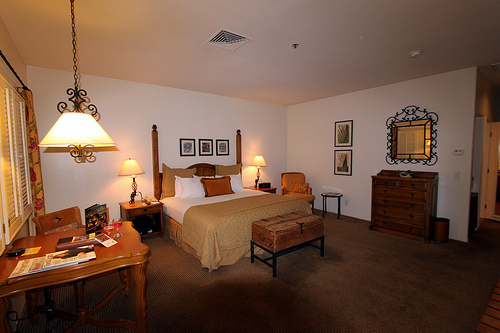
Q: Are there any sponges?
A: No, there are no sponges.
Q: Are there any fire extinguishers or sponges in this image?
A: No, there are no sponges or fire extinguishers.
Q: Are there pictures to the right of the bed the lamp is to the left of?
A: Yes, there is a picture to the right of the bed.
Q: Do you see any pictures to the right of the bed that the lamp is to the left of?
A: Yes, there is a picture to the right of the bed.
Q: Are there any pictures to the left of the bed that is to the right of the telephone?
A: No, the picture is to the right of the bed.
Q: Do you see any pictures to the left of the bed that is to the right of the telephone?
A: No, the picture is to the right of the bed.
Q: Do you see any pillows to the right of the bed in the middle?
A: No, there is a picture to the right of the bed.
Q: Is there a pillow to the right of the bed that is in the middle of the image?
A: No, there is a picture to the right of the bed.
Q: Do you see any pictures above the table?
A: Yes, there is a picture above the table.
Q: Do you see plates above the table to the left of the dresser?
A: No, there is a picture above the table.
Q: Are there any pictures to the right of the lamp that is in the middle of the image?
A: Yes, there is a picture to the right of the lamp.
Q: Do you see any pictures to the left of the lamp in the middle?
A: No, the picture is to the right of the lamp.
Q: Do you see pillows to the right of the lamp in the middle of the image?
A: No, there is a picture to the right of the lamp.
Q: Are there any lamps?
A: Yes, there is a lamp.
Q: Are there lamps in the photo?
A: Yes, there is a lamp.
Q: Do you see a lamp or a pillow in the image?
A: Yes, there is a lamp.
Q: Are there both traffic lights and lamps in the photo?
A: No, there is a lamp but no traffic lights.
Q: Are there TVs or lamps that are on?
A: Yes, the lamp is on.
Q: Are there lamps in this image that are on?
A: Yes, there is a lamp that is on.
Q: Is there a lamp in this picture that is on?
A: Yes, there is a lamp that is on.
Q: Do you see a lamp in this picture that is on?
A: Yes, there is a lamp that is on.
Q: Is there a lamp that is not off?
A: Yes, there is a lamp that is on.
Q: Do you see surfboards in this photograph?
A: No, there are no surfboards.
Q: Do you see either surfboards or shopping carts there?
A: No, there are no surfboards or shopping carts.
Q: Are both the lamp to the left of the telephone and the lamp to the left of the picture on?
A: Yes, both the lamp and the lamp are on.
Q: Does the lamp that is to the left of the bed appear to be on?
A: Yes, the lamp is on.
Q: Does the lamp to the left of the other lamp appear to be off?
A: No, the lamp is on.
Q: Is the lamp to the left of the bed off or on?
A: The lamp is on.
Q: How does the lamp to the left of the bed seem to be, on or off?
A: The lamp is on.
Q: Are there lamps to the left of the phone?
A: Yes, there is a lamp to the left of the phone.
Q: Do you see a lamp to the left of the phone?
A: Yes, there is a lamp to the left of the phone.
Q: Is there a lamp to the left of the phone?
A: Yes, there is a lamp to the left of the phone.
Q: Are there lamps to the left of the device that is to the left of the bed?
A: Yes, there is a lamp to the left of the phone.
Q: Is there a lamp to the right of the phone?
A: No, the lamp is to the left of the phone.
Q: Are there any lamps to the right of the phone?
A: No, the lamp is to the left of the phone.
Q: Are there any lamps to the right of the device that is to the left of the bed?
A: No, the lamp is to the left of the phone.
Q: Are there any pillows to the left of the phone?
A: No, there is a lamp to the left of the phone.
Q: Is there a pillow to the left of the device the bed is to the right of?
A: No, there is a lamp to the left of the phone.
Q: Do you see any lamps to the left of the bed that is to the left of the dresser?
A: Yes, there is a lamp to the left of the bed.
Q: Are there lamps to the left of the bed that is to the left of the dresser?
A: Yes, there is a lamp to the left of the bed.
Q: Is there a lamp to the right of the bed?
A: No, the lamp is to the left of the bed.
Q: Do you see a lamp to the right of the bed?
A: No, the lamp is to the left of the bed.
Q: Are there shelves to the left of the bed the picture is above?
A: No, there is a lamp to the left of the bed.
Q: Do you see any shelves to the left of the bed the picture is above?
A: No, there is a lamp to the left of the bed.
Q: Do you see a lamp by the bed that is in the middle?
A: Yes, there is a lamp by the bed.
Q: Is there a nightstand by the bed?
A: No, there is a lamp by the bed.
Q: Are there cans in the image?
A: Yes, there is a can.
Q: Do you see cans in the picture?
A: Yes, there is a can.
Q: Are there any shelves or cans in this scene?
A: Yes, there is a can.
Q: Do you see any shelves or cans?
A: Yes, there is a can.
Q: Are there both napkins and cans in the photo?
A: No, there is a can but no napkins.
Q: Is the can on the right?
A: Yes, the can is on the right of the image.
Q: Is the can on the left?
A: No, the can is on the right of the image.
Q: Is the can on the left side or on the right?
A: The can is on the right of the image.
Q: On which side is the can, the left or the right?
A: The can is on the right of the image.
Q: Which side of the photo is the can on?
A: The can is on the right of the image.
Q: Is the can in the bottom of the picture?
A: Yes, the can is in the bottom of the image.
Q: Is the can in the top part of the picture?
A: No, the can is in the bottom of the image.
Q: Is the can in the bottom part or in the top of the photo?
A: The can is in the bottom of the image.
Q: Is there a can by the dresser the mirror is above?
A: Yes, there is a can by the dresser.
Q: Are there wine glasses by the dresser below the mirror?
A: No, there is a can by the dresser.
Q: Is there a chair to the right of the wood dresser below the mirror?
A: No, there is a can to the right of the dresser.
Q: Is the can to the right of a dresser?
A: Yes, the can is to the right of a dresser.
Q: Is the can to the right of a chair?
A: No, the can is to the right of a dresser.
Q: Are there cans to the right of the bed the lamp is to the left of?
A: Yes, there is a can to the right of the bed.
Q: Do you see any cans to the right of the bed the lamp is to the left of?
A: Yes, there is a can to the right of the bed.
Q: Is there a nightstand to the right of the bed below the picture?
A: No, there is a can to the right of the bed.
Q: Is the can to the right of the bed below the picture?
A: Yes, the can is to the right of the bed.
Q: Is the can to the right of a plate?
A: No, the can is to the right of the bed.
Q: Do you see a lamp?
A: Yes, there is a lamp.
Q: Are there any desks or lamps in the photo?
A: Yes, there is a lamp.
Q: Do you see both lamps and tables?
A: Yes, there are both a lamp and a table.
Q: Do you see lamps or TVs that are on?
A: Yes, the lamp is on.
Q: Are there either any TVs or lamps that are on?
A: Yes, the lamp is on.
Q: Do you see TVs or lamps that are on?
A: Yes, the lamp is on.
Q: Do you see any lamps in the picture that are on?
A: Yes, there is a lamp that is on.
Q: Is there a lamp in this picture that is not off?
A: Yes, there is a lamp that is on.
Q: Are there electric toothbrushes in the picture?
A: No, there are no electric toothbrushes.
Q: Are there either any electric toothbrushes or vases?
A: No, there are no electric toothbrushes or vases.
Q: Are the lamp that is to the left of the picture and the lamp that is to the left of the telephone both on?
A: Yes, both the lamp and the lamp are on.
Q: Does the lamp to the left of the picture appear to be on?
A: Yes, the lamp is on.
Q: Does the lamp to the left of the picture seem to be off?
A: No, the lamp is on.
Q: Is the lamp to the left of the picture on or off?
A: The lamp is on.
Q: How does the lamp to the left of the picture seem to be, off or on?
A: The lamp is on.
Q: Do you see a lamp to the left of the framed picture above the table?
A: Yes, there is a lamp to the left of the picture.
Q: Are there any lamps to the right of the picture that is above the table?
A: No, the lamp is to the left of the picture.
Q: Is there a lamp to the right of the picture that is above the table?
A: No, the lamp is to the left of the picture.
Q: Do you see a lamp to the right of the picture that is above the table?
A: No, the lamp is to the left of the picture.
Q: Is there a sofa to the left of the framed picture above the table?
A: No, there is a lamp to the left of the picture.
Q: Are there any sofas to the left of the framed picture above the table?
A: No, there is a lamp to the left of the picture.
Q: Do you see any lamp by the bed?
A: Yes, there is a lamp by the bed.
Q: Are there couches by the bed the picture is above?
A: No, there is a lamp by the bed.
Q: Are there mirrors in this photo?
A: Yes, there is a mirror.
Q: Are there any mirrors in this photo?
A: Yes, there is a mirror.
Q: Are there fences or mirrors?
A: Yes, there is a mirror.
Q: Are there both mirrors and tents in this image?
A: No, there is a mirror but no tents.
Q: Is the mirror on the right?
A: Yes, the mirror is on the right of the image.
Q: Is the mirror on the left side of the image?
A: No, the mirror is on the right of the image.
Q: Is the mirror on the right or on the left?
A: The mirror is on the right of the image.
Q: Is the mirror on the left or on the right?
A: The mirror is on the right of the image.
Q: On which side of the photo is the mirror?
A: The mirror is on the right of the image.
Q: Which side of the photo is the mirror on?
A: The mirror is on the right of the image.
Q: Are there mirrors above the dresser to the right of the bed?
A: Yes, there is a mirror above the dresser.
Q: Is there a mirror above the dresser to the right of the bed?
A: Yes, there is a mirror above the dresser.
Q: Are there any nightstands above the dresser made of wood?
A: No, there is a mirror above the dresser.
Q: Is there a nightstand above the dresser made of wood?
A: No, there is a mirror above the dresser.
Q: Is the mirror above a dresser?
A: Yes, the mirror is above a dresser.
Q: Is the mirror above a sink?
A: No, the mirror is above a dresser.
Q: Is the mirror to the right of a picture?
A: Yes, the mirror is to the right of a picture.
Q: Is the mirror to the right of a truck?
A: No, the mirror is to the right of a picture.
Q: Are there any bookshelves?
A: No, there are no bookshelves.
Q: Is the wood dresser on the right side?
A: Yes, the dresser is on the right of the image.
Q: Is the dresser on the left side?
A: No, the dresser is on the right of the image.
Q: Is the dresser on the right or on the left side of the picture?
A: The dresser is on the right of the image.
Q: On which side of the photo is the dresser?
A: The dresser is on the right of the image.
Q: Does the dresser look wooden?
A: Yes, the dresser is wooden.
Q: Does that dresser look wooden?
A: Yes, the dresser is wooden.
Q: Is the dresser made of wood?
A: Yes, the dresser is made of wood.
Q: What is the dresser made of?
A: The dresser is made of wood.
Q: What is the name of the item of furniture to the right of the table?
A: The piece of furniture is a dresser.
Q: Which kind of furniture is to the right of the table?
A: The piece of furniture is a dresser.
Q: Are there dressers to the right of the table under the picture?
A: Yes, there is a dresser to the right of the table.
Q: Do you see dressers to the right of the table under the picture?
A: Yes, there is a dresser to the right of the table.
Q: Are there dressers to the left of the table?
A: No, the dresser is to the right of the table.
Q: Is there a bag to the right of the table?
A: No, there is a dresser to the right of the table.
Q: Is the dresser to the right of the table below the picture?
A: Yes, the dresser is to the right of the table.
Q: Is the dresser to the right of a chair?
A: No, the dresser is to the right of the table.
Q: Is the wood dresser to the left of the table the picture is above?
A: No, the dresser is to the right of the table.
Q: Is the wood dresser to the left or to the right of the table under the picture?
A: The dresser is to the right of the table.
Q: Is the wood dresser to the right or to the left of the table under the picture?
A: The dresser is to the right of the table.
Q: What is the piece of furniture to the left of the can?
A: The piece of furniture is a dresser.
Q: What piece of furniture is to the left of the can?
A: The piece of furniture is a dresser.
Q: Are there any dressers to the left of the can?
A: Yes, there is a dresser to the left of the can.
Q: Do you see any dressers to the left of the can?
A: Yes, there is a dresser to the left of the can.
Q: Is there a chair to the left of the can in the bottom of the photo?
A: No, there is a dresser to the left of the can.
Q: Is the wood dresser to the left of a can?
A: Yes, the dresser is to the left of a can.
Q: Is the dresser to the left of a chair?
A: No, the dresser is to the left of a can.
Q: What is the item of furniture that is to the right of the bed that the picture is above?
A: The piece of furniture is a dresser.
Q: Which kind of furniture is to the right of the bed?
A: The piece of furniture is a dresser.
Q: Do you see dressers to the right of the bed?
A: Yes, there is a dresser to the right of the bed.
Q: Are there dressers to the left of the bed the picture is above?
A: No, the dresser is to the right of the bed.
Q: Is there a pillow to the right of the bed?
A: No, there is a dresser to the right of the bed.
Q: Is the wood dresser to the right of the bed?
A: Yes, the dresser is to the right of the bed.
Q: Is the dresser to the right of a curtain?
A: No, the dresser is to the right of the bed.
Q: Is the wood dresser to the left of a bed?
A: No, the dresser is to the right of a bed.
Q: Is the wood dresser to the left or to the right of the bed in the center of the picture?
A: The dresser is to the right of the bed.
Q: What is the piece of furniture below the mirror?
A: The piece of furniture is a dresser.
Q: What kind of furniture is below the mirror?
A: The piece of furniture is a dresser.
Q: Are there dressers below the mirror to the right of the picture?
A: Yes, there is a dresser below the mirror.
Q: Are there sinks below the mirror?
A: No, there is a dresser below the mirror.